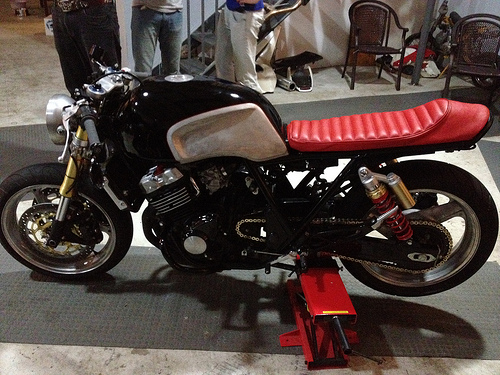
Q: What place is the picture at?
A: It is at the pavement.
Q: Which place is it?
A: It is a pavement.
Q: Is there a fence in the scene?
A: No, there are no fences.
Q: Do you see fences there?
A: No, there are no fences.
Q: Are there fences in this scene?
A: No, there are no fences.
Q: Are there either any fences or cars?
A: No, there are no fences or cars.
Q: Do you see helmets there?
A: No, there are no helmets.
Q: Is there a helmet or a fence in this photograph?
A: No, there are no helmets or fences.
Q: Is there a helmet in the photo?
A: No, there are no helmets.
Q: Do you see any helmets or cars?
A: No, there are no helmets or cars.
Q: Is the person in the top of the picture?
A: Yes, the person is in the top of the image.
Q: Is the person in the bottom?
A: No, the person is in the top of the image.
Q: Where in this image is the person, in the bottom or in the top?
A: The person is in the top of the image.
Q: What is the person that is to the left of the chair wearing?
A: The person is wearing trousers.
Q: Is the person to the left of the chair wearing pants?
A: Yes, the person is wearing pants.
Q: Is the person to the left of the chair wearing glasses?
A: No, the person is wearing pants.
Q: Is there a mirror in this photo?
A: No, there are no mirrors.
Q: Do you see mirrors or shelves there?
A: No, there are no mirrors or shelves.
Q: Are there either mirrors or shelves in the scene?
A: No, there are no mirrors or shelves.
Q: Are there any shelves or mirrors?
A: No, there are no mirrors or shelves.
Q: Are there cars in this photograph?
A: No, there are no cars.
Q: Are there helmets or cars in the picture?
A: No, there are no cars or helmets.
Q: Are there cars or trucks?
A: No, there are no cars or trucks.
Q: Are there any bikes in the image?
A: Yes, there is a bike.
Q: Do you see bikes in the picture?
A: Yes, there is a bike.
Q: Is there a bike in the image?
A: Yes, there is a bike.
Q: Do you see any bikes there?
A: Yes, there is a bike.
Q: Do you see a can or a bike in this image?
A: Yes, there is a bike.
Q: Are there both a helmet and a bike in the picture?
A: No, there is a bike but no helmets.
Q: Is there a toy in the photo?
A: No, there are no toys.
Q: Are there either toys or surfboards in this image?
A: No, there are no toys or surfboards.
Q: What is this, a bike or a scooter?
A: This is a bike.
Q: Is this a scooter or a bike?
A: This is a bike.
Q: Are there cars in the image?
A: No, there are no cars.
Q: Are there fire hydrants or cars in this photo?
A: No, there are no cars or fire hydrants.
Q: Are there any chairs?
A: Yes, there is a chair.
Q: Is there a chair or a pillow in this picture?
A: Yes, there is a chair.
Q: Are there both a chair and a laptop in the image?
A: No, there is a chair but no laptops.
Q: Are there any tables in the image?
A: No, there are no tables.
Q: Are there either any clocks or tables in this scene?
A: No, there are no tables or clocks.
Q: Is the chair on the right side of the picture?
A: Yes, the chair is on the right of the image.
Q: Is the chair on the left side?
A: No, the chair is on the right of the image.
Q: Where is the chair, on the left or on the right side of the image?
A: The chair is on the right of the image.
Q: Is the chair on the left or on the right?
A: The chair is on the right of the image.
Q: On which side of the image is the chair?
A: The chair is on the right of the image.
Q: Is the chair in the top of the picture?
A: Yes, the chair is in the top of the image.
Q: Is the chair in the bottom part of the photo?
A: No, the chair is in the top of the image.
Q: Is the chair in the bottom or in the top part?
A: The chair is in the top of the image.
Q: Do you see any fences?
A: No, there are no fences.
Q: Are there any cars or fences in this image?
A: No, there are no fences or cars.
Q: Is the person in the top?
A: Yes, the person is in the top of the image.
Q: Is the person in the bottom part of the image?
A: No, the person is in the top of the image.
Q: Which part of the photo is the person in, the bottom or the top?
A: The person is in the top of the image.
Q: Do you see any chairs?
A: Yes, there is a chair.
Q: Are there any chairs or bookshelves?
A: Yes, there is a chair.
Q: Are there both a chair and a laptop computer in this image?
A: No, there is a chair but no laptops.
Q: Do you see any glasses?
A: No, there are no glasses.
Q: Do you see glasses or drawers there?
A: No, there are no glasses or drawers.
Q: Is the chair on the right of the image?
A: Yes, the chair is on the right of the image.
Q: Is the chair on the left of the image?
A: No, the chair is on the right of the image.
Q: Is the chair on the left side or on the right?
A: The chair is on the right of the image.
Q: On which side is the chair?
A: The chair is on the right of the image.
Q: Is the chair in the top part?
A: Yes, the chair is in the top of the image.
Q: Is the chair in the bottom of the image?
A: No, the chair is in the top of the image.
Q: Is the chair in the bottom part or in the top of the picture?
A: The chair is in the top of the image.